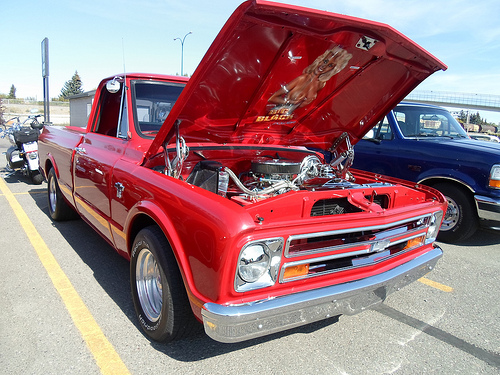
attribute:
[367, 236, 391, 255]
logo — silver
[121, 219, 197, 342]
tire — black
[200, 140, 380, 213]
engine — silver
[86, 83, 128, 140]
window — open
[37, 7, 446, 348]
car — red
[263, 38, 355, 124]
woman — partially naked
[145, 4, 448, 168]
hood — upright, truck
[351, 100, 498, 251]
truck — blue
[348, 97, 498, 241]
truck — blue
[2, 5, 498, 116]
sky — light blue, cloudy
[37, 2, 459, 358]
truck — red, shiny, pickup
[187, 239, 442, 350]
bumper — silver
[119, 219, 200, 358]
tire — passenger side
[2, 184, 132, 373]
line — yellow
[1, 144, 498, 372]
lot — parking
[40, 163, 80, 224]
tire — back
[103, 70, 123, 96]
mirror — side view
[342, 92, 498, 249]
truck — blue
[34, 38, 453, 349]
truck — blue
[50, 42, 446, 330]
truck — red 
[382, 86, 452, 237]
car — blue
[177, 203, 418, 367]
bumper — silver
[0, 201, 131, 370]
line — yellow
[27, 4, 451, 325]
car — red